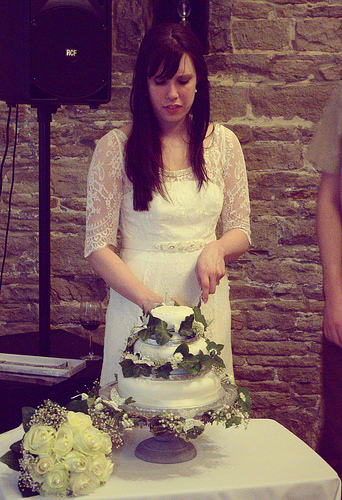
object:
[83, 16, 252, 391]
woman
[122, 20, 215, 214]
hair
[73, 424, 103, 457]
rose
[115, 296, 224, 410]
cake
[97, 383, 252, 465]
stand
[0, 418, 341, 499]
table cloth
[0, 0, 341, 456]
wall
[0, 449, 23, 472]
leaf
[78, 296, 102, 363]
glass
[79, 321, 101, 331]
drink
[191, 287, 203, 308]
knife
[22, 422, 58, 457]
rose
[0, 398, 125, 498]
bouquet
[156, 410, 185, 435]
flower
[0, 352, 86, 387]
gift box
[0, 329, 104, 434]
table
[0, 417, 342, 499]
table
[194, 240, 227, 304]
left hand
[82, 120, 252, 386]
bridal gown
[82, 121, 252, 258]
lace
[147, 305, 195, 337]
layer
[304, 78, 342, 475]
person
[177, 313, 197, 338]
leaf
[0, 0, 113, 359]
speaker